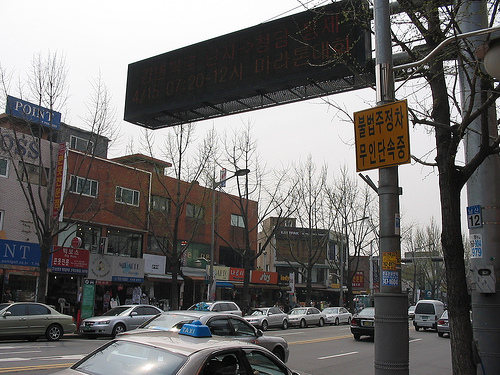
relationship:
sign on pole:
[355, 108, 411, 161] [372, 6, 404, 313]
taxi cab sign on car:
[174, 324, 211, 338] [59, 331, 292, 373]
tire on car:
[50, 325, 61, 338] [1, 304, 75, 336]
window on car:
[80, 346, 172, 374] [59, 331, 292, 373]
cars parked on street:
[4, 304, 347, 324] [1, 324, 457, 374]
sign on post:
[355, 108, 411, 161] [372, 6, 404, 313]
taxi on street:
[59, 331, 292, 373] [1, 324, 457, 374]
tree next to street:
[269, 153, 344, 306] [1, 324, 457, 374]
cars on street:
[4, 304, 347, 324] [1, 324, 457, 374]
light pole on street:
[209, 171, 248, 303] [1, 324, 457, 374]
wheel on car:
[259, 322, 270, 329] [244, 307, 293, 327]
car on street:
[147, 312, 288, 356] [1, 324, 457, 374]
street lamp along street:
[209, 171, 248, 303] [1, 324, 457, 374]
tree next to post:
[324, 6, 488, 374] [372, 6, 404, 313]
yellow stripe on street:
[280, 335, 355, 346] [1, 324, 457, 374]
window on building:
[114, 185, 141, 206] [55, 149, 259, 307]